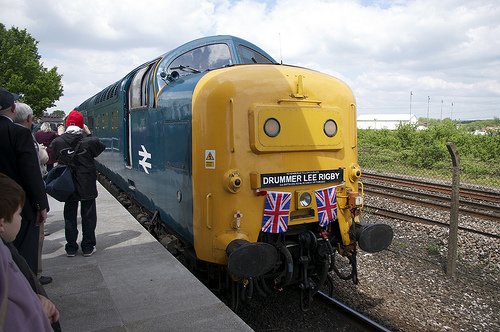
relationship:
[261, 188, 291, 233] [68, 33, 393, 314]
flag on train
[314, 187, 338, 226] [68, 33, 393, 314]
flag on train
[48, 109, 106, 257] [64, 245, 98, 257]
man wearing shoes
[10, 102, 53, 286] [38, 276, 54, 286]
man wearing shoes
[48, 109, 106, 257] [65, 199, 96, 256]
man wearing pants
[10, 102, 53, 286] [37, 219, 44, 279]
man wearing pants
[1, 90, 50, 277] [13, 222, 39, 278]
man wearing pants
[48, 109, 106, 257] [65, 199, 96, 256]
man wearing jeans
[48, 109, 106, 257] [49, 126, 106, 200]
man wearing jacket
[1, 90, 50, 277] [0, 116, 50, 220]
man wearing jacket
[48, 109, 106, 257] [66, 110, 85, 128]
man wearing hat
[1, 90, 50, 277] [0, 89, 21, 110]
man wearing hat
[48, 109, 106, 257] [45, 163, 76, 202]
man carrying bag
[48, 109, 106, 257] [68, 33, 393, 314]
man waiting for train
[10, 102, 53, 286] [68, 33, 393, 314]
man waiting for train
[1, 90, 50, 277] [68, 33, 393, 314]
man waiting for train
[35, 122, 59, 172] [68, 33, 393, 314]
person waiting for train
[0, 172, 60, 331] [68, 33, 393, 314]
person waiting for train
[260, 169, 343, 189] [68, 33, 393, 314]
name sign on train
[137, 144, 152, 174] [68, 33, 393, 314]
logo on train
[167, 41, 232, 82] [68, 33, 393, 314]
window on train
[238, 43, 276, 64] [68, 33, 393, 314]
window on train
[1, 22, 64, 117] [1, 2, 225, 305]
tree on side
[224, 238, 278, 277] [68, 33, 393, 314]
speaker on train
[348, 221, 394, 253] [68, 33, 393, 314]
speaker on train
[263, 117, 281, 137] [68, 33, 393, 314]
light on train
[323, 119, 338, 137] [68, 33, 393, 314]
light on train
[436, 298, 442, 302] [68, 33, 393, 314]
rock by train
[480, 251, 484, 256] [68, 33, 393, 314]
rock by train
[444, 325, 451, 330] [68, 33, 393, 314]
rock by train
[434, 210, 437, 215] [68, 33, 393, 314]
rock by train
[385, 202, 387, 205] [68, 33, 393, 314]
rock by train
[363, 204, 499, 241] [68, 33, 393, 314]
track by train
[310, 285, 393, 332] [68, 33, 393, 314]
track by train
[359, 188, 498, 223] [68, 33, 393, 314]
track by train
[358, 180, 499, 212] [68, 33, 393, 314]
track by train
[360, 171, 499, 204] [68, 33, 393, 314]
track by train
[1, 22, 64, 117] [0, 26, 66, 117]
tree in distance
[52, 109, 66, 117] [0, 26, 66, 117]
tree in distance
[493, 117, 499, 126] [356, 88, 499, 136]
tree in distance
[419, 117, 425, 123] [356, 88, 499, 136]
tree in distance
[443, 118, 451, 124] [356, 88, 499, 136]
tree in distance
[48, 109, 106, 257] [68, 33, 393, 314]
man next to train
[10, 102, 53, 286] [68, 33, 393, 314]
man next to train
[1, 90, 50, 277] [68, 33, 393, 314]
man next to train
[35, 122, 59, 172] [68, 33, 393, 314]
person next to train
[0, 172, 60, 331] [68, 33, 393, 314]
person next to train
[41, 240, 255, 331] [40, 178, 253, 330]
shadow on ground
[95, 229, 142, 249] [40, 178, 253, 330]
shadow on ground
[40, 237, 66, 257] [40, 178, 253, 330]
shadow on ground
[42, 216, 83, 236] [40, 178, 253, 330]
shadow on ground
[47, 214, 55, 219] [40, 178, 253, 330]
shadow on ground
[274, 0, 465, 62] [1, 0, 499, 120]
cloud in sky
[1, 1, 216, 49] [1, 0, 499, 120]
cloud in sky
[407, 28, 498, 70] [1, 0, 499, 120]
cloud in sky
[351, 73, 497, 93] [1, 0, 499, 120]
cloud in sky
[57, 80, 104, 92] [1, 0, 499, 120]
cloud in sky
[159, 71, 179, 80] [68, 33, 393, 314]
horn on train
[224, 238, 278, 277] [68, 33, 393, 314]
bumper on train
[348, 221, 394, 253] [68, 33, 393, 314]
bumper on train